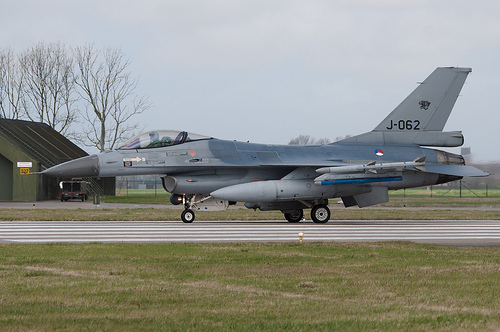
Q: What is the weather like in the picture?
A: It is overcast.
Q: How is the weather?
A: It is overcast.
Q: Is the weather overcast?
A: Yes, it is overcast.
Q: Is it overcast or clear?
A: It is overcast.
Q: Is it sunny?
A: No, it is overcast.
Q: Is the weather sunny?
A: No, it is overcast.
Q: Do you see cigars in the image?
A: No, there are no cigars.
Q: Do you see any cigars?
A: No, there are no cigars.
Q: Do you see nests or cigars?
A: No, there are no cigars or nests.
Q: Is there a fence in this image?
A: No, there are no fences.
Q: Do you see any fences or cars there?
A: No, there are no fences or cars.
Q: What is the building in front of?
A: The building is in front of the tree.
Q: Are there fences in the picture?
A: No, there are no fences.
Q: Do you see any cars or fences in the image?
A: No, there are no fences or cars.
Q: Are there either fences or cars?
A: No, there are no fences or cars.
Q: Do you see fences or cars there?
A: No, there are no fences or cars.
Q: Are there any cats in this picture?
A: No, there are no cats.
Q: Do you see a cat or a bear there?
A: No, there are no cats or bears.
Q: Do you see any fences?
A: No, there are no fences.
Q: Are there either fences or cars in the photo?
A: No, there are no fences or cars.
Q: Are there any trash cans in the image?
A: No, there are no trash cans.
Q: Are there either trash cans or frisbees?
A: No, there are no trash cans or frisbees.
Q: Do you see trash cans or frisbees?
A: No, there are no trash cans or frisbees.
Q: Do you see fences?
A: No, there are no fences.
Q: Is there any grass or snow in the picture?
A: Yes, there is grass.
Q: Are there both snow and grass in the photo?
A: No, there is grass but no snow.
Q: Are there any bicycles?
A: No, there are no bicycles.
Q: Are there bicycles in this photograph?
A: No, there are no bicycles.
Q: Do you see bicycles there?
A: No, there are no bicycles.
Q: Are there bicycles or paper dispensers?
A: No, there are no bicycles or paper dispensers.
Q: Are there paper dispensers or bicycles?
A: No, there are no bicycles or paper dispensers.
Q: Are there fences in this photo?
A: No, there are no fences.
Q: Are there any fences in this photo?
A: No, there are no fences.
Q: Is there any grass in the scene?
A: Yes, there is grass.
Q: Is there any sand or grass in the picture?
A: Yes, there is grass.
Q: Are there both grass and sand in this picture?
A: No, there is grass but no sand.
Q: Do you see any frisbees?
A: No, there are no frisbees.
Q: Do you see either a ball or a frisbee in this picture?
A: No, there are no frisbees or balls.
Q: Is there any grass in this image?
A: Yes, there is grass.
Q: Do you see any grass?
A: Yes, there is grass.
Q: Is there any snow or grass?
A: Yes, there is grass.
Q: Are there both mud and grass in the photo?
A: No, there is grass but no mud.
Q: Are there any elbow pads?
A: No, there are no elbow pads.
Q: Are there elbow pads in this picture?
A: No, there are no elbow pads.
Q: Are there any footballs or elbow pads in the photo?
A: No, there are no elbow pads or footballs.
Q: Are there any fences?
A: No, there are no fences.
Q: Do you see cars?
A: No, there are no cars.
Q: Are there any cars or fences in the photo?
A: No, there are no cars or fences.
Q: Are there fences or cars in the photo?
A: No, there are no cars or fences.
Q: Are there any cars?
A: No, there are no cars.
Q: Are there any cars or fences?
A: No, there are no cars or fences.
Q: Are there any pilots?
A: Yes, there is a pilot.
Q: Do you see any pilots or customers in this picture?
A: Yes, there is a pilot.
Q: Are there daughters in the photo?
A: No, there are no daughters.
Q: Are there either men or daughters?
A: No, there are no daughters or men.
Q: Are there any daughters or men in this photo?
A: No, there are no daughters or men.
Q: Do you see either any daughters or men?
A: No, there are no daughters or men.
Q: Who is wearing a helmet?
A: The pilot is wearing a helmet.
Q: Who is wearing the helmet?
A: The pilot is wearing a helmet.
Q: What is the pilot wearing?
A: The pilot is wearing a helmet.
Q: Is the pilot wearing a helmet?
A: Yes, the pilot is wearing a helmet.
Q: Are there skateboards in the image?
A: No, there are no skateboards.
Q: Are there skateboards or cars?
A: No, there are no skateboards or cars.